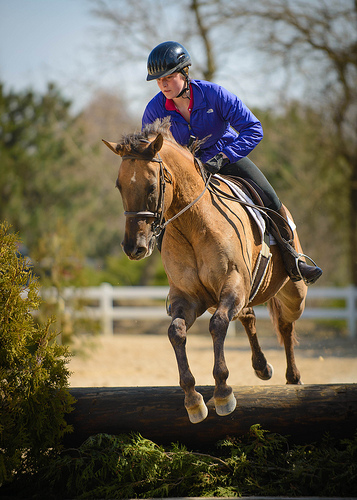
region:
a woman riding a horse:
[43, 33, 339, 317]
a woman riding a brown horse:
[65, 69, 308, 309]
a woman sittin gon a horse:
[71, 9, 337, 370]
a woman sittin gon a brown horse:
[77, 52, 353, 411]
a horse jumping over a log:
[72, 102, 336, 476]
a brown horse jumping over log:
[92, 155, 328, 431]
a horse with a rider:
[94, 16, 324, 367]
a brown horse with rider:
[48, 72, 355, 423]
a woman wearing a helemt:
[148, 20, 252, 161]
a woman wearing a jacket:
[132, 28, 324, 233]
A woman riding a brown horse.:
[100, 41, 321, 425]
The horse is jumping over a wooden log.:
[0, 114, 356, 448]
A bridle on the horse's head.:
[99, 133, 171, 259]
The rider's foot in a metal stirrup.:
[283, 253, 323, 285]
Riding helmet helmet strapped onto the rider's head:
[144, 41, 191, 100]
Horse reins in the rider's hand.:
[159, 149, 226, 232]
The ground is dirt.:
[53, 296, 354, 385]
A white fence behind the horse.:
[12, 284, 356, 340]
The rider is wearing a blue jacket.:
[141, 78, 263, 162]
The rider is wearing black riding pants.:
[222, 142, 281, 219]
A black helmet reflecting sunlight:
[146, 40, 190, 80]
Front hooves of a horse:
[182, 391, 237, 422]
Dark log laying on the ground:
[57, 382, 348, 457]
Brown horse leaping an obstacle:
[103, 138, 302, 421]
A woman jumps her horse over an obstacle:
[104, 37, 311, 422]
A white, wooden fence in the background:
[14, 285, 352, 336]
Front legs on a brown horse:
[164, 277, 236, 423]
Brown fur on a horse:
[194, 208, 242, 273]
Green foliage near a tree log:
[0, 232, 58, 491]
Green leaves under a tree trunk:
[59, 442, 349, 493]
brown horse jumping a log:
[98, 116, 303, 420]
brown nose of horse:
[122, 215, 154, 260]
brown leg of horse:
[210, 278, 254, 414]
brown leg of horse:
[167, 297, 208, 422]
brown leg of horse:
[275, 281, 297, 381]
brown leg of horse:
[240, 301, 271, 380]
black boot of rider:
[286, 257, 316, 288]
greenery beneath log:
[33, 438, 347, 499]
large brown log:
[59, 383, 355, 439]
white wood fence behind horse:
[30, 274, 355, 333]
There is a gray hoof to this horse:
[217, 388, 250, 457]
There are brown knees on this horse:
[167, 315, 179, 339]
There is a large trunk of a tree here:
[127, 384, 141, 438]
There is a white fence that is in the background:
[131, 283, 142, 329]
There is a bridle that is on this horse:
[129, 203, 151, 247]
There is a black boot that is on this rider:
[284, 242, 329, 316]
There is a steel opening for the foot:
[292, 260, 310, 288]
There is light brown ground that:
[105, 346, 113, 371]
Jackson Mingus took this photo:
[66, 250, 165, 465]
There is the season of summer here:
[90, 264, 212, 453]